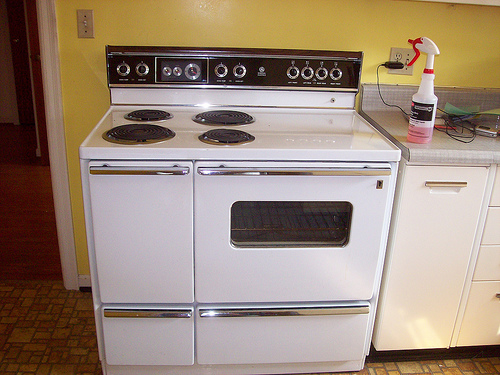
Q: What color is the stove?
A: White, black, and brown.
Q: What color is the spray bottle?
A: White and red.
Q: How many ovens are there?
A: One.